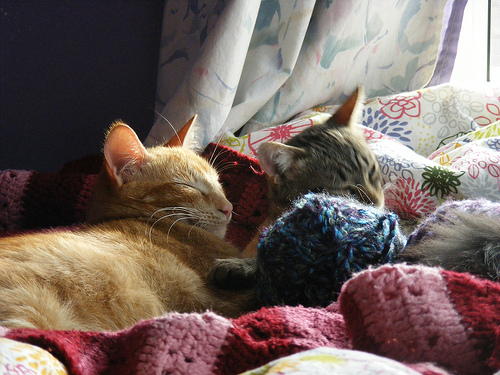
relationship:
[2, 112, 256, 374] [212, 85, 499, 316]
cat next to cat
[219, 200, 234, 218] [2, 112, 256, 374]
nose of cat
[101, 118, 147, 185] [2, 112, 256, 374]
ear on cat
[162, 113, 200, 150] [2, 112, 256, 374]
ear on cat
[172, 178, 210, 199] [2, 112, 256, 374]
eye of cat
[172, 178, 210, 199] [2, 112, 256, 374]
eye on cat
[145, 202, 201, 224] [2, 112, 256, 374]
whisker on cat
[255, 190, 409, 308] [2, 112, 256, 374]
yarn in front of cat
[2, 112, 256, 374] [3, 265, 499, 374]
cat laying on blanket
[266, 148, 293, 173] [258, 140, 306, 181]
hair in ear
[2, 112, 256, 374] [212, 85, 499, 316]
cat laying down next to cat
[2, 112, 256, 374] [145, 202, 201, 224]
cat has whisker